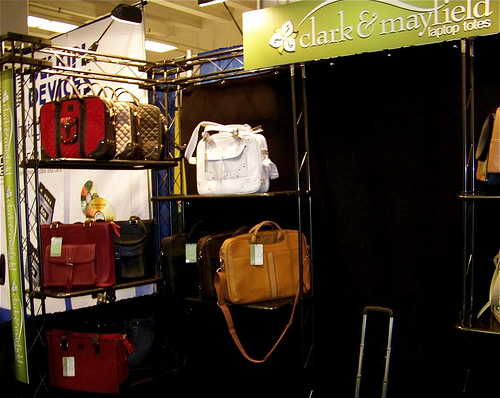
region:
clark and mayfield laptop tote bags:
[243, 9, 496, 58]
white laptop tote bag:
[185, 116, 293, 200]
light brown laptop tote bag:
[219, 228, 311, 308]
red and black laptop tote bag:
[37, 95, 119, 165]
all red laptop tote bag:
[40, 218, 122, 288]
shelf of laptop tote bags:
[26, 64, 183, 396]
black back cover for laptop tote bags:
[182, 76, 499, 396]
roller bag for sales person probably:
[351, 302, 400, 397]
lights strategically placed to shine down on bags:
[110, 4, 154, 28]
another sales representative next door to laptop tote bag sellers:
[13, 6, 158, 320]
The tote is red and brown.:
[28, 79, 118, 165]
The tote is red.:
[33, 209, 124, 299]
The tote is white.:
[174, 106, 284, 206]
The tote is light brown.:
[216, 215, 318, 374]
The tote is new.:
[22, 73, 118, 165]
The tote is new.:
[35, 203, 122, 304]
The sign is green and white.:
[241, 0, 498, 80]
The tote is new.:
[37, 302, 137, 397]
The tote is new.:
[89, 200, 173, 290]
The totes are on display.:
[3, 32, 351, 397]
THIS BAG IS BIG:
[175, 112, 277, 203]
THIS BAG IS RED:
[33, 305, 139, 391]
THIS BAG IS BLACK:
[103, 205, 154, 290]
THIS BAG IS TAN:
[80, 90, 171, 163]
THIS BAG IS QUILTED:
[102, 85, 167, 165]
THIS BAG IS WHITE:
[167, 110, 287, 200]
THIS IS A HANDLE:
[330, 292, 401, 394]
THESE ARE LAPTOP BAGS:
[25, 68, 320, 394]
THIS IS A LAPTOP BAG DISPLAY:
[2, 26, 325, 394]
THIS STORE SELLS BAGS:
[2, 0, 497, 397]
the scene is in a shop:
[9, 3, 497, 379]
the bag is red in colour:
[41, 318, 139, 393]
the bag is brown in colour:
[221, 228, 311, 335]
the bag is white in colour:
[193, 97, 283, 189]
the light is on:
[83, 2, 160, 33]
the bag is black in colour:
[119, 215, 169, 276]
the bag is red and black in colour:
[40, 92, 120, 164]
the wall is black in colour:
[343, 139, 395, 284]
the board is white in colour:
[64, 179, 117, 204]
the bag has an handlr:
[303, 278, 392, 395]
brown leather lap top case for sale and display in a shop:
[216, 220, 322, 362]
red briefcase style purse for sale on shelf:
[46, 322, 130, 390]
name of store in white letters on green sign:
[231, 3, 499, 79]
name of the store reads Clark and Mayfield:
[241, 2, 498, 78]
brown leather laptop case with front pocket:
[32, 217, 114, 292]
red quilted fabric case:
[35, 95, 120, 158]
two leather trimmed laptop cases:
[106, 95, 172, 160]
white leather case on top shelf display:
[180, 115, 280, 191]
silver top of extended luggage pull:
[348, 295, 396, 390]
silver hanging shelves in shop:
[3, 32, 498, 394]